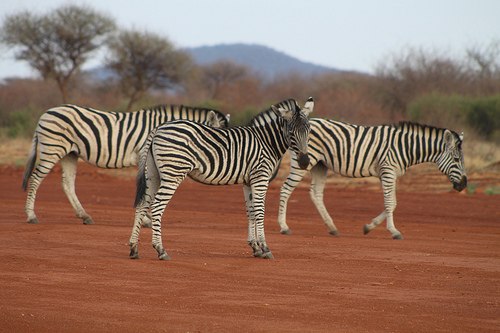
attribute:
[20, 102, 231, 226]
zebra — black, white, walking, striped, playing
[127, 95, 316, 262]
zebra — playing, black, white, walking, looking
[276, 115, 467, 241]
zebra — black, white, walking, playing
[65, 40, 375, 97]
hill — distant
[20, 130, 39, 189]
tail — hairy, striped, long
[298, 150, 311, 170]
snout — solid black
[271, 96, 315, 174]
head — tilted, pointed down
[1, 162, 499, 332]
ground — dirt, red, clay, rust colored, brown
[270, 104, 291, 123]
ear — pointy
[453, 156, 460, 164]
eye — black, small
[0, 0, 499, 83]
sky — light blue, pale blue, overcast, blue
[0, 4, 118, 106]
tree — distant, brown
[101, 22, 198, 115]
tree — distant, brown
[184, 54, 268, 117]
tree — brown, distant